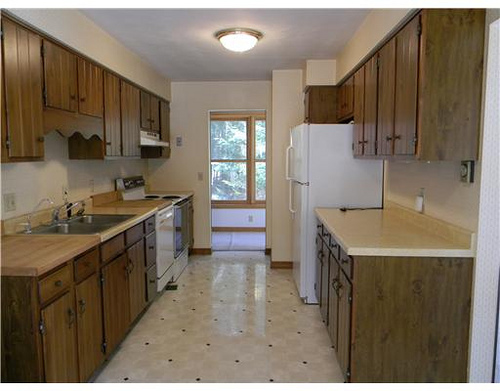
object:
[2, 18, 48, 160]
cabinet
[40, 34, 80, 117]
cabinet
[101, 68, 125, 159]
cabinet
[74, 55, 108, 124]
cabinet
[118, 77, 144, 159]
cabinet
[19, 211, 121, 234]
sink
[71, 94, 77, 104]
knob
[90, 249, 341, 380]
floor tile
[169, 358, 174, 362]
black circle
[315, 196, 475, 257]
countertop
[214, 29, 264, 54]
light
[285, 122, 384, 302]
refrigerator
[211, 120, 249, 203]
window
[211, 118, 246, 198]
trees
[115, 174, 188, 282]
stove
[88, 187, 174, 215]
countertop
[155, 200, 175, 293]
dishwasher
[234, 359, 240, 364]
black circle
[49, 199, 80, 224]
faucet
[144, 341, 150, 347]
black circle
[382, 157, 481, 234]
wall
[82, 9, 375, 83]
ceiling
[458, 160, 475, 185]
switch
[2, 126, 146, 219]
wall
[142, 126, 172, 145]
hood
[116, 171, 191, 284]
range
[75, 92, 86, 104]
knob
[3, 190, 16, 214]
light switch